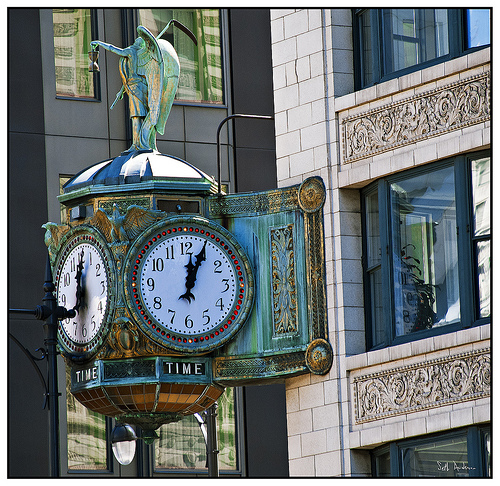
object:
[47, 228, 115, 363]
clock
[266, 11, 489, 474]
house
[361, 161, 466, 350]
window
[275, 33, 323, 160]
wall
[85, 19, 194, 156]
sculpture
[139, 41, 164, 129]
wings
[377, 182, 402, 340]
curtain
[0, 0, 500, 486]
building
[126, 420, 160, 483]
pole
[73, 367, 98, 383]
time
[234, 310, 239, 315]
dog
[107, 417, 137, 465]
light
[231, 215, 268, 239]
green